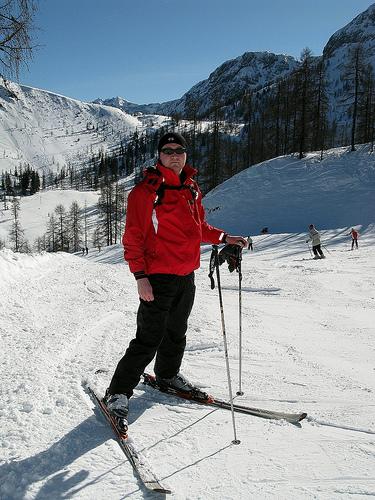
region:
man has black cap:
[151, 136, 186, 159]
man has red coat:
[103, 161, 231, 314]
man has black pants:
[77, 232, 231, 400]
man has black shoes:
[68, 381, 149, 437]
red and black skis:
[87, 383, 231, 496]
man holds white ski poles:
[182, 238, 292, 481]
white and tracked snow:
[39, 246, 116, 429]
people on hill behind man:
[195, 211, 352, 289]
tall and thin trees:
[190, 47, 356, 203]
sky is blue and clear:
[93, 14, 176, 79]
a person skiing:
[305, 223, 332, 259]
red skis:
[77, 376, 311, 492]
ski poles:
[211, 245, 249, 444]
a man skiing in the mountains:
[102, 129, 247, 416]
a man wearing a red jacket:
[102, 131, 246, 412]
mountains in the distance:
[0, 25, 371, 176]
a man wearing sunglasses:
[102, 131, 241, 391]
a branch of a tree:
[0, 0, 39, 78]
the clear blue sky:
[50, 4, 195, 79]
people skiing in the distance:
[305, 217, 362, 258]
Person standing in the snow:
[87, 100, 271, 498]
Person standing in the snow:
[242, 228, 262, 262]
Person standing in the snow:
[256, 211, 277, 256]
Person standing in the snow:
[286, 214, 321, 262]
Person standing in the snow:
[343, 218, 363, 260]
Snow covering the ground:
[242, 463, 277, 496]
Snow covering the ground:
[281, 467, 310, 498]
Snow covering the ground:
[317, 466, 345, 491]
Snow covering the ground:
[309, 337, 335, 376]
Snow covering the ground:
[15, 318, 48, 356]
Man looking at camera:
[99, 120, 251, 429]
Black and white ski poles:
[209, 233, 259, 445]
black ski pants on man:
[98, 261, 203, 409]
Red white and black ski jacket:
[123, 163, 233, 287]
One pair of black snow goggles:
[155, 142, 191, 159]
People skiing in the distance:
[195, 189, 361, 273]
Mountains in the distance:
[71, 1, 374, 136]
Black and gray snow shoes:
[97, 352, 209, 439]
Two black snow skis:
[55, 344, 317, 498]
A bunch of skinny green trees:
[0, 41, 373, 263]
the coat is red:
[178, 213, 196, 246]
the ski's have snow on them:
[81, 375, 105, 399]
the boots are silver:
[156, 369, 194, 393]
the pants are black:
[156, 285, 169, 314]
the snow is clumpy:
[12, 380, 47, 414]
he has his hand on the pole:
[226, 231, 248, 261]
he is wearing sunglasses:
[161, 145, 189, 155]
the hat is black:
[157, 131, 187, 146]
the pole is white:
[217, 341, 237, 406]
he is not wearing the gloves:
[131, 275, 159, 303]